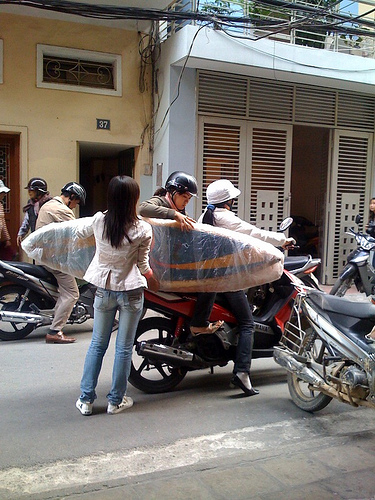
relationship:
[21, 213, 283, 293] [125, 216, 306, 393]
big board on back of gmotorcycle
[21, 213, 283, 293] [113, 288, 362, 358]
big board on back motorcycle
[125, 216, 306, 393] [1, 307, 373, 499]
gmotorcycle on street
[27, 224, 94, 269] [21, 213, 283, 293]
plastic bag on big board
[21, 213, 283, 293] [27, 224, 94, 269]
big board has plastic bag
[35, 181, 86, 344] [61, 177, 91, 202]
guy wearing helmet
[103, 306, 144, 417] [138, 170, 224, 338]
leg of girl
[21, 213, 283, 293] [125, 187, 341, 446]
big board of motorcycle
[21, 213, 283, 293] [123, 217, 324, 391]
big board of motorcycle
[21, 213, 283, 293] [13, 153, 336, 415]
big board of motorcycle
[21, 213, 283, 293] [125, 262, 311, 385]
big board of gmotorcycle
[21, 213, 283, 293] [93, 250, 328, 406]
big board of motorcycle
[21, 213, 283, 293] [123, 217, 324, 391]
big board on motorcycle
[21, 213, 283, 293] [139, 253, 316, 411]
big board on motorcycle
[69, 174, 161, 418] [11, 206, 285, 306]
girl holding surfboard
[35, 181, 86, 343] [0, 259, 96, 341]
guy on gmotorcycle